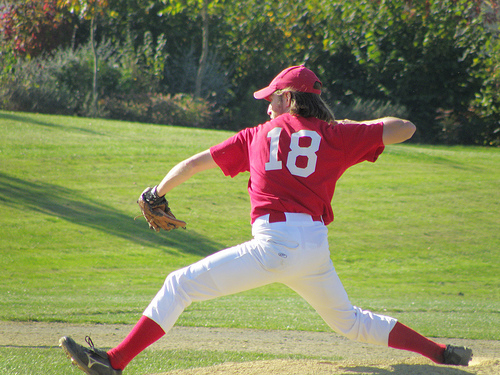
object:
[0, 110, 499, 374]
ground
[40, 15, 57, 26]
leaves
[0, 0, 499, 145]
tree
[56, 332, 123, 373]
baseball cleats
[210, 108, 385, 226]
t-shirt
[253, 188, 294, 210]
red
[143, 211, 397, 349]
pants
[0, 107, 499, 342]
lawn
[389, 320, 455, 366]
socks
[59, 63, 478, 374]
man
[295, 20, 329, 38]
leaves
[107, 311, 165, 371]
sock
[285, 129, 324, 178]
number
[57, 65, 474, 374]
pitching stance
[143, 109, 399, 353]
uniform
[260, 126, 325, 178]
eighteen